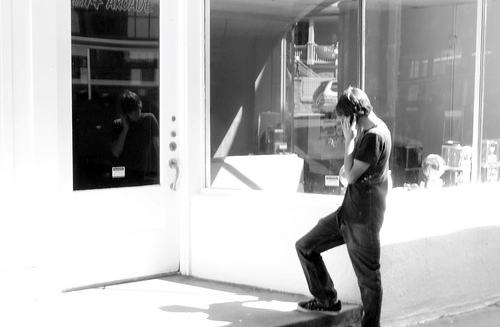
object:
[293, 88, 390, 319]
boy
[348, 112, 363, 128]
phone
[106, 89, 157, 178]
reflection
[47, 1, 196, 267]
door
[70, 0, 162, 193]
glass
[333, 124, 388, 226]
teeshirt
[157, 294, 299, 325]
shadow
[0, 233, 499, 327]
ground